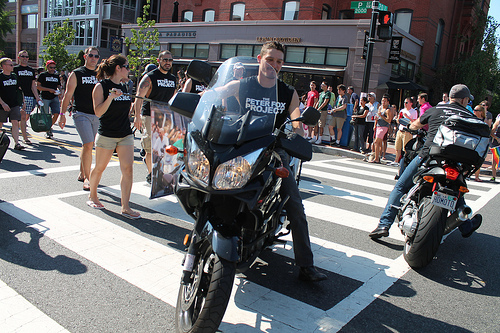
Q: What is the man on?
A: A Motorcycle.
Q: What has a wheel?
A: A motorcycle.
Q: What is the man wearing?
A: Blue Jeans.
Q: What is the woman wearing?
A: Flip flops and shorts.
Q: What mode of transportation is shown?
A: Motorcycles.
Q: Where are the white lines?
A: Street.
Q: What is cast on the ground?
A: Shadows.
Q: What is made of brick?
A: Building.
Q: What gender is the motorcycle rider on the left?
A: Male.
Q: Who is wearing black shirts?
A: Motorcycle rider on the left and the people on the left.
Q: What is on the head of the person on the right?
A: Cap.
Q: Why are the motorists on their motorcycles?
A: Ready to ride.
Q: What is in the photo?
A: Motorcycles.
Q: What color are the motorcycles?
A: Black.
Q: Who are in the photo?
A: People.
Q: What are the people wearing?
A: T shirts.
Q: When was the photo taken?
A: Daytime.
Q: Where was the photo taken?
A: On the street.